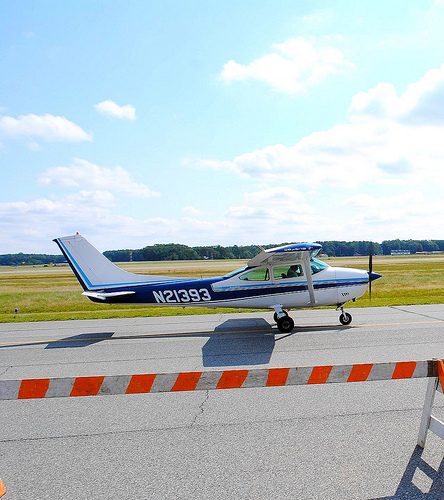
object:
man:
[287, 265, 299, 278]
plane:
[50, 230, 384, 334]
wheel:
[339, 312, 353, 326]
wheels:
[277, 316, 295, 334]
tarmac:
[0, 302, 444, 500]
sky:
[0, 0, 444, 255]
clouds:
[0, 110, 94, 153]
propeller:
[368, 241, 373, 305]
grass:
[332, 261, 444, 308]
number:
[163, 290, 177, 303]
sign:
[0, 359, 444, 499]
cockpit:
[273, 256, 329, 280]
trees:
[231, 244, 242, 260]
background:
[0, 0, 444, 268]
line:
[0, 318, 444, 345]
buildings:
[390, 249, 410, 256]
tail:
[52, 232, 198, 289]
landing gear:
[268, 299, 353, 334]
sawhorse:
[416, 358, 444, 450]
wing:
[246, 243, 323, 267]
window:
[237, 267, 271, 282]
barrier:
[0, 355, 444, 401]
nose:
[367, 272, 382, 282]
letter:
[152, 290, 166, 303]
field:
[0, 254, 444, 323]